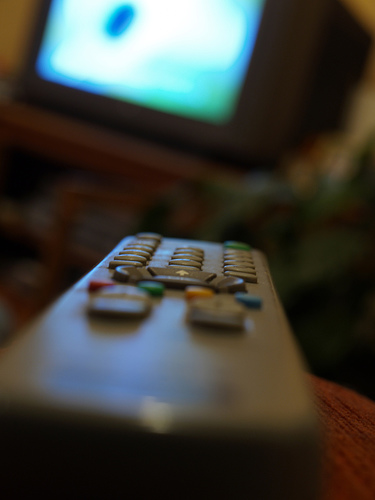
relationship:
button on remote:
[193, 305, 246, 336] [2, 229, 326, 480]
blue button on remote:
[234, 291, 261, 311] [2, 229, 326, 480]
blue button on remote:
[234, 291, 261, 311] [5, 204, 350, 498]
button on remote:
[134, 279, 164, 302] [7, 220, 322, 442]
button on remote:
[86, 273, 109, 292] [4, 192, 349, 471]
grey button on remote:
[131, 229, 160, 244] [2, 229, 326, 480]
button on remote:
[86, 278, 119, 296] [2, 229, 326, 480]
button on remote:
[225, 235, 250, 252] [68, 212, 371, 480]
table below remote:
[324, 388, 354, 441] [2, 226, 341, 498]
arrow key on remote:
[156, 261, 220, 279] [19, 209, 312, 452]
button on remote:
[86, 278, 119, 296] [7, 220, 322, 442]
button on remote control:
[134, 279, 164, 302] [0, 229, 324, 499]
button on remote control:
[185, 286, 213, 301] [0, 229, 324, 499]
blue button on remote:
[234, 291, 261, 311] [93, 202, 301, 394]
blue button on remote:
[238, 287, 263, 306] [117, 225, 275, 386]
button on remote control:
[185, 286, 213, 301] [0, 233, 319, 498]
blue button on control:
[234, 291, 261, 311] [109, 338, 238, 387]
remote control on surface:
[12, 229, 324, 463] [6, 282, 362, 496]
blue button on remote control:
[234, 291, 261, 311] [4, 215, 329, 490]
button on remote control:
[133, 272, 212, 306] [0, 229, 324, 499]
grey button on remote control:
[222, 268, 256, 283] [15, 165, 336, 497]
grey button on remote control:
[222, 247, 256, 254] [15, 165, 336, 497]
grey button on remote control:
[131, 236, 161, 244] [15, 165, 336, 497]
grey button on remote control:
[119, 260, 144, 284] [15, 165, 336, 497]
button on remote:
[184, 284, 215, 301] [2, 229, 326, 480]